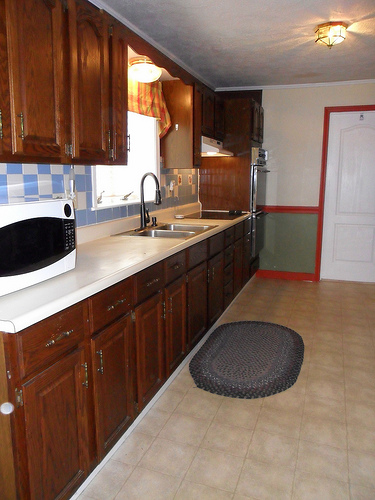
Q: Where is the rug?
A: Floor.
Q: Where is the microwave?
A: Counter.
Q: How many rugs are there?
A: One.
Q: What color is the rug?
A: Gray.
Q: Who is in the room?
A: No one.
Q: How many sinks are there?
A: Two.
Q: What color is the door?
A: White.